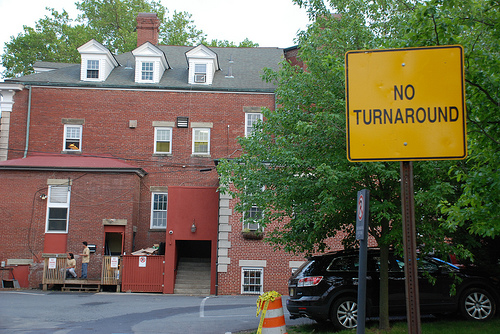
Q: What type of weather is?
A: It is overcast.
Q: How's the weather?
A: It is overcast.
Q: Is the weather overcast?
A: Yes, it is overcast.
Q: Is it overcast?
A: Yes, it is overcast.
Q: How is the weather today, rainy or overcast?
A: It is overcast.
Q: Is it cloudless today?
A: No, it is overcast.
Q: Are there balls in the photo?
A: No, there are no balls.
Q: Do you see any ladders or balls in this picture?
A: No, there are no balls or ladders.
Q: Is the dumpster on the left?
A: Yes, the dumpster is on the left of the image.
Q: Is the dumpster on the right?
A: No, the dumpster is on the left of the image.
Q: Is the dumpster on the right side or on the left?
A: The dumpster is on the left of the image.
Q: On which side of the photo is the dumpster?
A: The dumpster is on the left of the image.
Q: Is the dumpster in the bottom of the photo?
A: Yes, the dumpster is in the bottom of the image.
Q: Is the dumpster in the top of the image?
A: No, the dumpster is in the bottom of the image.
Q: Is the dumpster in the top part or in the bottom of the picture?
A: The dumpster is in the bottom of the image.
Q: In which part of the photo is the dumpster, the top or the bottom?
A: The dumpster is in the bottom of the image.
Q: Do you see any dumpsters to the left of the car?
A: Yes, there is a dumpster to the left of the car.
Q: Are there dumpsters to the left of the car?
A: Yes, there is a dumpster to the left of the car.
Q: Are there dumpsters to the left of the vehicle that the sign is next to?
A: Yes, there is a dumpster to the left of the car.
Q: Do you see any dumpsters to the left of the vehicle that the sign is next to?
A: Yes, there is a dumpster to the left of the car.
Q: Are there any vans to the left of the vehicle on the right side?
A: No, there is a dumpster to the left of the car.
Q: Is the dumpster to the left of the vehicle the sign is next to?
A: Yes, the dumpster is to the left of the car.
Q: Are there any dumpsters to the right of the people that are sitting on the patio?
A: Yes, there is a dumpster to the right of the people.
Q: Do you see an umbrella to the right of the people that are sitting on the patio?
A: No, there is a dumpster to the right of the people.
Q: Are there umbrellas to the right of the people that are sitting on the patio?
A: No, there is a dumpster to the right of the people.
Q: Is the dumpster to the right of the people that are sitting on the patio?
A: Yes, the dumpster is to the right of the people.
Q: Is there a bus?
A: No, there are no buses.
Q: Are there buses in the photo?
A: No, there are no buses.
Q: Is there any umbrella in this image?
A: No, there are no umbrellas.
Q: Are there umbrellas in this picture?
A: No, there are no umbrellas.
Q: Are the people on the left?
A: Yes, the people are on the left of the image.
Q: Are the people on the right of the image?
A: No, the people are on the left of the image.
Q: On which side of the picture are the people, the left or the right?
A: The people are on the left of the image.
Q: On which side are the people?
A: The people are on the left of the image.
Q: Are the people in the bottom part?
A: Yes, the people are in the bottom of the image.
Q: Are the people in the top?
A: No, the people are in the bottom of the image.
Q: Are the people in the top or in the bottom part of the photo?
A: The people are in the bottom of the image.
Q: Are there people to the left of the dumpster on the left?
A: Yes, there are people to the left of the dumpster.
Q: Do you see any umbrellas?
A: No, there are no umbrellas.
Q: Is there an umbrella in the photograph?
A: No, there are no umbrellas.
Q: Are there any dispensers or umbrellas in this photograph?
A: No, there are no umbrellas or dispensers.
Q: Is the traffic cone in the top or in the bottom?
A: The traffic cone is in the bottom of the image.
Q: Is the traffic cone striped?
A: Yes, the traffic cone is striped.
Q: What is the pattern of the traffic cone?
A: The traffic cone is striped.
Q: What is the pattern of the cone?
A: The traffic cone is striped.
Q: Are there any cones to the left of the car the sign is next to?
A: Yes, there is a cone to the left of the car.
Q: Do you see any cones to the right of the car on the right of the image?
A: No, the cone is to the left of the car.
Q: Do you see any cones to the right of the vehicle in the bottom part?
A: No, the cone is to the left of the car.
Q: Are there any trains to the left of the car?
A: No, there is a cone to the left of the car.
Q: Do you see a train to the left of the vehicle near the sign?
A: No, there is a cone to the left of the car.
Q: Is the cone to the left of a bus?
A: No, the cone is to the left of a car.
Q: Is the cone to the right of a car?
A: No, the cone is to the left of a car.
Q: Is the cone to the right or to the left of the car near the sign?
A: The cone is to the left of the car.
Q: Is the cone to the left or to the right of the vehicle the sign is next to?
A: The cone is to the left of the car.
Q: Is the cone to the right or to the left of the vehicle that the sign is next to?
A: The cone is to the left of the car.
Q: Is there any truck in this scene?
A: No, there are no trucks.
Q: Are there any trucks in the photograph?
A: No, there are no trucks.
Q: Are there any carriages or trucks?
A: No, there are no trucks or carriages.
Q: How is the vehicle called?
A: The vehicle is a car.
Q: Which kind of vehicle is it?
A: The vehicle is a car.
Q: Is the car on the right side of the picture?
A: Yes, the car is on the right of the image.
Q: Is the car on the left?
A: No, the car is on the right of the image.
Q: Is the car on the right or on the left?
A: The car is on the right of the image.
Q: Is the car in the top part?
A: No, the car is in the bottom of the image.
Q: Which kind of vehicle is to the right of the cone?
A: The vehicle is a car.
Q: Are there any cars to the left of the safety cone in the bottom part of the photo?
A: No, the car is to the right of the traffic cone.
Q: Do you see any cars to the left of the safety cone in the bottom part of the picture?
A: No, the car is to the right of the traffic cone.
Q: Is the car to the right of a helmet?
A: No, the car is to the right of a cone.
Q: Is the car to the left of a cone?
A: No, the car is to the right of a cone.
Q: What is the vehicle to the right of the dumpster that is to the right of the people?
A: The vehicle is a car.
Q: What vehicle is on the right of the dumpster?
A: The vehicle is a car.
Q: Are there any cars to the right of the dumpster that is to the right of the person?
A: Yes, there is a car to the right of the dumpster.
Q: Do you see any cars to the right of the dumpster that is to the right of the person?
A: Yes, there is a car to the right of the dumpster.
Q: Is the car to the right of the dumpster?
A: Yes, the car is to the right of the dumpster.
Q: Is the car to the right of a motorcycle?
A: No, the car is to the right of the dumpster.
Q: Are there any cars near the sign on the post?
A: Yes, there is a car near the sign.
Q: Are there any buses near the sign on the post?
A: No, there is a car near the sign.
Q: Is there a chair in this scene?
A: No, there are no chairs.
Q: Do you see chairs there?
A: No, there are no chairs.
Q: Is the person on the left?
A: Yes, the person is on the left of the image.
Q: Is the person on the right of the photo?
A: No, the person is on the left of the image.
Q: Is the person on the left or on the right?
A: The person is on the left of the image.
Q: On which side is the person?
A: The person is on the left of the image.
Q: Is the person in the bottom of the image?
A: Yes, the person is in the bottom of the image.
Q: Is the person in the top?
A: No, the person is in the bottom of the image.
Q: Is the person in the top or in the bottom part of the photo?
A: The person is in the bottom of the image.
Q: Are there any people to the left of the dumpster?
A: Yes, there is a person to the left of the dumpster.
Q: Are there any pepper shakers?
A: No, there are no pepper shakers.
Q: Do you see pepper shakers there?
A: No, there are no pepper shakers.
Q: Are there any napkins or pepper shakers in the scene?
A: No, there are no pepper shakers or napkins.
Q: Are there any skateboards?
A: No, there are no skateboards.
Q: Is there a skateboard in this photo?
A: No, there are no skateboards.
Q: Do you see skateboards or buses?
A: No, there are no skateboards or buses.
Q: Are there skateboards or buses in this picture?
A: No, there are no skateboards or buses.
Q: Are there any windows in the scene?
A: Yes, there is a window.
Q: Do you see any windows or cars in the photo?
A: Yes, there is a window.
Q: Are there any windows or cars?
A: Yes, there is a window.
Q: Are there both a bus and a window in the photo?
A: No, there is a window but no buses.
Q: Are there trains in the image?
A: No, there are no trains.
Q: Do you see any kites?
A: No, there are no kites.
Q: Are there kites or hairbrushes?
A: No, there are no kites or hairbrushes.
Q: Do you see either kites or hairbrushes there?
A: No, there are no kites or hairbrushes.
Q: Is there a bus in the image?
A: No, there are no buses.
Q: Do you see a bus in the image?
A: No, there are no buses.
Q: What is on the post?
A: The sign is on the post.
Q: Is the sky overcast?
A: Yes, the sky is overcast.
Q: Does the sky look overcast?
A: Yes, the sky is overcast.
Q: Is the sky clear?
A: No, the sky is overcast.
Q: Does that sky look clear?
A: No, the sky is overcast.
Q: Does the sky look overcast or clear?
A: The sky is overcast.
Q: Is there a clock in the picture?
A: No, there are no clocks.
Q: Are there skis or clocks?
A: No, there are no clocks or skis.